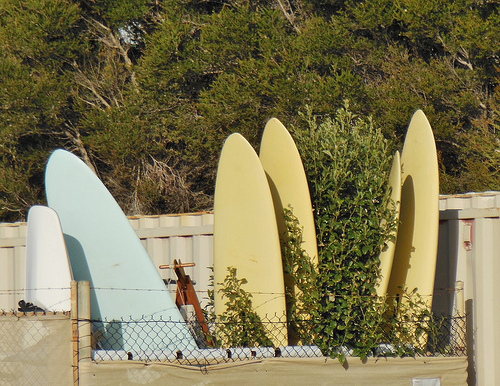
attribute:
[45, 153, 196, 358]
surfboard — light blue, blue, sky blue, small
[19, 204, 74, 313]
surfboard — white, small, short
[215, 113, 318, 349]
surfboards — yellow, pale yellow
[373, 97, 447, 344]
surfboards — yellow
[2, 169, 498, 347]
wall — brown, metal, white, beige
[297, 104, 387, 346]
bush — tall, large, green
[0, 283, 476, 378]
fence — chain link, wire, metal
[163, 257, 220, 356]
pulley — red, metal, brown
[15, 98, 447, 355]
surfboards — colorful, standing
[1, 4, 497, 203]
trees — green, grouped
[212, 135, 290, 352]
surfboard — pale yellow, light yellow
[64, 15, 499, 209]
branches — brown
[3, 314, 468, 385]
tarp — brown